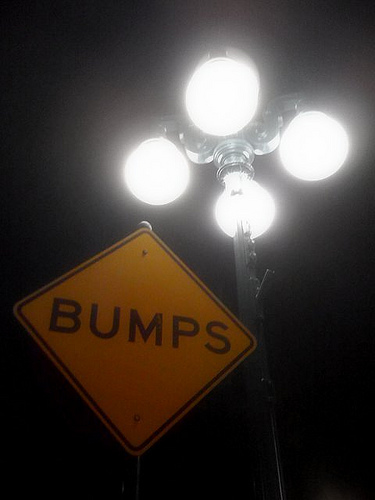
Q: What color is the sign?
A: Yellow.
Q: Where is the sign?
A: Under the street light.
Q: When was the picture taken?
A: At night.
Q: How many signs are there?
A: One.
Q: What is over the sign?
A: The street light.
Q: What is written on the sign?
A: Bumps.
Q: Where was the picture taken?
A: Beside streetlights.